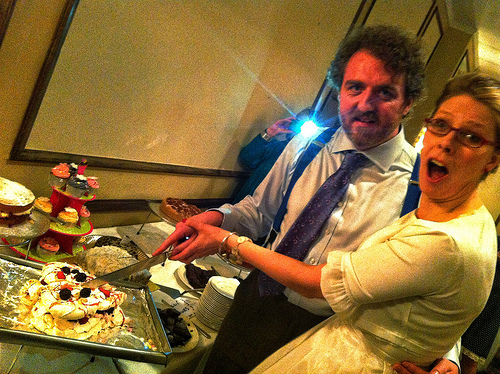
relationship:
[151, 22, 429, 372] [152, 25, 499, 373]
man standing with woman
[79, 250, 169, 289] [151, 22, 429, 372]
knife held by man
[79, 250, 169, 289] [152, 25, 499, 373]
knife held by woman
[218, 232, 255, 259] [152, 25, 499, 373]
bracelet worn by woman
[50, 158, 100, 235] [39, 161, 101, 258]
cupcake on display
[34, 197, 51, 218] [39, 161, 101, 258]
cupcake on display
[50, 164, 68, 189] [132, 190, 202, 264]
cupcake on display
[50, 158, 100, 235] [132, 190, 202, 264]
cupcake on display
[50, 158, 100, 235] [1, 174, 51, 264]
cupcake on display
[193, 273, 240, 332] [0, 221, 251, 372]
plates on table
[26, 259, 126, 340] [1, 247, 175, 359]
dessert on foil pan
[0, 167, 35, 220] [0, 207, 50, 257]
layer cake on tray stand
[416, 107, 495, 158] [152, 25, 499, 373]
glasses worn by woman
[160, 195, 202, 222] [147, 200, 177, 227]
pie on a tray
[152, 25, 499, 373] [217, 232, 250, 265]
woman wearing bracelets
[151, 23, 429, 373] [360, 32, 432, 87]
man with curly hair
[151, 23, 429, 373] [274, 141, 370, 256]
man wearing tie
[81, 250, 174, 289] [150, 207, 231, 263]
knife in hands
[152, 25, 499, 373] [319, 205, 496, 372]
woman wearing dress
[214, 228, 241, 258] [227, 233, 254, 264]
bracelet on bracelet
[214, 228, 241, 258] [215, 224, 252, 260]
bracelet on wrist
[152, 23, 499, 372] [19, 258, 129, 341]
couple holding cake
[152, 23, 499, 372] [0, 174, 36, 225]
couple holding cake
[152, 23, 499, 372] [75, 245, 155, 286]
couple holding cake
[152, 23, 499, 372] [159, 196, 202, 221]
couple holding cake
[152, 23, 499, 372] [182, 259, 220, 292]
couple holding cake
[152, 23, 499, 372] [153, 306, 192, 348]
couple holding cake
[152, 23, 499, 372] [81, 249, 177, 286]
couple holding knife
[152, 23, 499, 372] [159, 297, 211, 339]
couple holding knife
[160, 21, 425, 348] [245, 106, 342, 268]
guy wearing suspenders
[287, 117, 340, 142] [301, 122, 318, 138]
camera with flash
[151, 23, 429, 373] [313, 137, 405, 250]
man in shirt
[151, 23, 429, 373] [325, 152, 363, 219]
man in tie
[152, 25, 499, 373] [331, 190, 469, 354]
woman in dress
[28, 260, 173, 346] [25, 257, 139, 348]
cake with cake frosting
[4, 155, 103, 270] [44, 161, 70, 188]
tower with cupcake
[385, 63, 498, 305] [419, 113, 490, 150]
woman wearing glasses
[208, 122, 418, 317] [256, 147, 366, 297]
shirt with tie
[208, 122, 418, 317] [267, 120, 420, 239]
shirt with suspenders